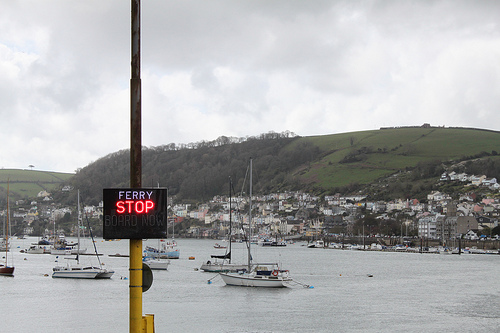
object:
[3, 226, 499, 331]
water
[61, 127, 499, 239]
countryside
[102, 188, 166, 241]
signal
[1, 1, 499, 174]
clouds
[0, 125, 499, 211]
hill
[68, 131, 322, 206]
trees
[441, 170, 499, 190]
houses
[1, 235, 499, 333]
ocean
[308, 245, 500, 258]
pier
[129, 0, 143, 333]
pole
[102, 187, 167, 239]
sign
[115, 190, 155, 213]
text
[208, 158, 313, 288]
sailboat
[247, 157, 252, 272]
tall mast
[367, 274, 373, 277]
duck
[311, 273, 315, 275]
duck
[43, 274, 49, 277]
duck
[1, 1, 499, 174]
sky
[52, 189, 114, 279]
sailboat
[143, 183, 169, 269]
sailboat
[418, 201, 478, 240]
building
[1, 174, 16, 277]
sailboat